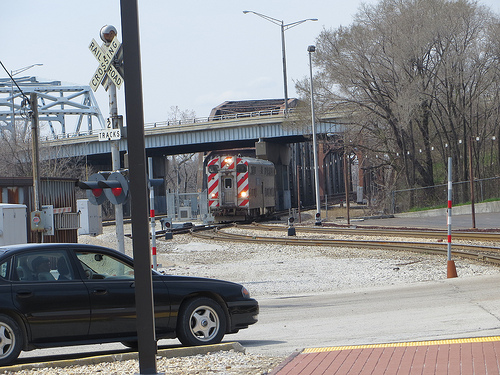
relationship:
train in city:
[195, 147, 284, 229] [8, 6, 490, 374]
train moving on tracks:
[195, 147, 284, 229] [124, 221, 265, 247]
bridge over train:
[22, 108, 357, 160] [204, 155, 276, 217]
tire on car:
[175, 291, 229, 348] [0, 243, 260, 366]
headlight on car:
[240, 283, 252, 300] [0, 239, 132, 357]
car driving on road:
[0, 243, 260, 366] [2, 283, 497, 366]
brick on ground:
[296, 350, 498, 374] [228, 247, 437, 289]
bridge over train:
[2, 71, 383, 163] [207, 151, 276, 224]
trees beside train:
[280, 0, 500, 215] [198, 137, 294, 238]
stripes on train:
[202, 158, 225, 206] [206, 154, 279, 214]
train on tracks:
[195, 147, 284, 229] [222, 210, 491, 262]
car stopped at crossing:
[13, 216, 293, 322] [289, 220, 498, 373]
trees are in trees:
[291, 3, 495, 220] [280, 0, 500, 215]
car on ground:
[0, 243, 260, 366] [0, 201, 500, 375]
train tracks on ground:
[123, 190, 498, 263] [56, 212, 499, 298]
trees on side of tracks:
[280, 0, 500, 215] [179, 221, 212, 233]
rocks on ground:
[162, 243, 320, 282] [56, 212, 499, 298]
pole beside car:
[105, 0, 175, 372] [0, 243, 260, 366]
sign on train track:
[94, 113, 125, 143] [189, 219, 499, 276]